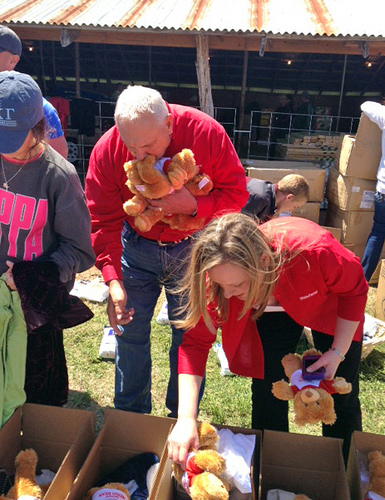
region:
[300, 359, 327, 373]
the lady is holding the phone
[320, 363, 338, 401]
the lady is holding the bear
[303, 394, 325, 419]
the bear is brown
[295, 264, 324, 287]
the shirt is red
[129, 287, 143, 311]
the pants are blue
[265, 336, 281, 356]
the pants are black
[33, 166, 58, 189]
the shirt is gray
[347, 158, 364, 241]
the boxes are stacked up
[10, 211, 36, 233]
the letters are pink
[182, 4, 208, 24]
the roof is rusty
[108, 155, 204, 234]
man is holding teddy bears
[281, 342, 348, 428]
woman has a teddy bear in her hand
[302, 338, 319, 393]
the woman is holding her cell phone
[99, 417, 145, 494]
box with stuffed animals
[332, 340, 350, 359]
woman is wearing a watch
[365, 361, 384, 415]
the grass behind the woman is green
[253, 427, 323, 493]
box is in shadow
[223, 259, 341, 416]
woman is leaning over the boxes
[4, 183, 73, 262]
large pink letters on the shirt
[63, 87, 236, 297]
man is carrying stuffed toys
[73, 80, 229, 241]
man is carrying stuffed toys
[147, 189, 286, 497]
woman putting toy in a box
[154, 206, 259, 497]
woman putting toy in a box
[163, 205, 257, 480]
woman putting toy in a box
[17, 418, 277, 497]
teddy bears in the boxes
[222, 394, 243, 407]
the grass is short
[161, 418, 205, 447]
hand of the woman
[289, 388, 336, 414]
the teddy bear's face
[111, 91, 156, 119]
hair on the head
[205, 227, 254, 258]
hair on the head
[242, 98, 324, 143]
gate in the barn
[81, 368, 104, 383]
sun on the grass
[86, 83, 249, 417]
a man holding teddy bears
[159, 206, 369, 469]
a woman holding a teddy bear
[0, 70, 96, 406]
a woman in a blue hat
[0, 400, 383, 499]
boxes filled with teddy bears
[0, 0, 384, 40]
a rusted and metal roof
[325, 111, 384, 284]
stacks of square boxes